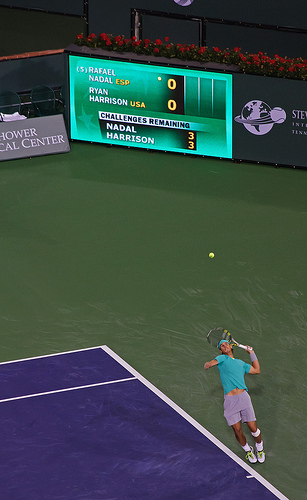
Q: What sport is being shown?
A: Tennis.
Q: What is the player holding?
A: Tennis racket.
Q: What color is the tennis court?
A: Blue.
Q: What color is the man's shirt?
A: Aqua.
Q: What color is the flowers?
A: Red.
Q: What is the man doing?
A: Serving.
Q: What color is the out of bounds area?
A: Green.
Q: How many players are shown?
A: One.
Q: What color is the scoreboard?
A: Green.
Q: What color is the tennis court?
A: Blue.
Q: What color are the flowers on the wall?
A: Red.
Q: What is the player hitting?
A: Tennis ball.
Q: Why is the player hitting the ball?
A: To win.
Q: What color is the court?
A: Blue.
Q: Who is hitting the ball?
A: The tennis player.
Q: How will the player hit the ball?
A: Hard.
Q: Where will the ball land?
A: On the other side.